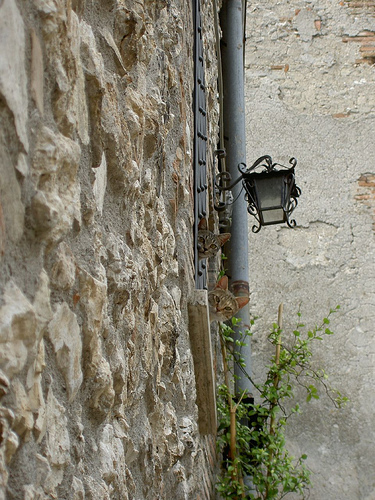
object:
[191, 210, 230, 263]
cats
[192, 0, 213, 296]
window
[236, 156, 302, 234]
lamp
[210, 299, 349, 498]
plant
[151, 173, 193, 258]
building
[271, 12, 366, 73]
wall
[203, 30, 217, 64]
sill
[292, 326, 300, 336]
leaves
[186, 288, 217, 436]
ledge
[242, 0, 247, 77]
bars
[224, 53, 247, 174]
pipe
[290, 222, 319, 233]
bricks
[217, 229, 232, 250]
ears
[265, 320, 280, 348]
leaf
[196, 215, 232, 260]
head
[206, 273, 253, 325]
cat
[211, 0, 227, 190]
pole